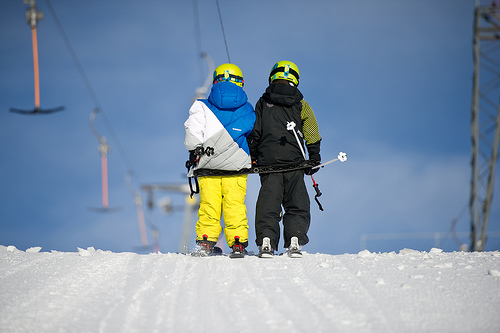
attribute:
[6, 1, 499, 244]
sky — here, blue, beautiful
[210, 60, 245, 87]
helmet — here, yellow, safety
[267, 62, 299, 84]
helmet — here, yellow, safety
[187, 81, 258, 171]
jacket — here, blue, white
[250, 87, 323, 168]
jacket — black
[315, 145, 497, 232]
clouds — here, white, light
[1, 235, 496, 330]
snow — here, white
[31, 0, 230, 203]
wire — here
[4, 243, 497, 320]
ground — covered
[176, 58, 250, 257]
person — standing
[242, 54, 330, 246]
person — standing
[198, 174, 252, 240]
snowpants — yellow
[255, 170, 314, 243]
snowpants — black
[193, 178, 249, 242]
pants — yellow, ski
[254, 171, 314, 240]
pants — black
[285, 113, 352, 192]
poles — white, ski, pair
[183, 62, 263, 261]
skier — standing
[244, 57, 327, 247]
skier — standing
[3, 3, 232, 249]
ski lift — here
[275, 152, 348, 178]
pole — ski, used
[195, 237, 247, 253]
boots — black, ski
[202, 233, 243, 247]
trim — red